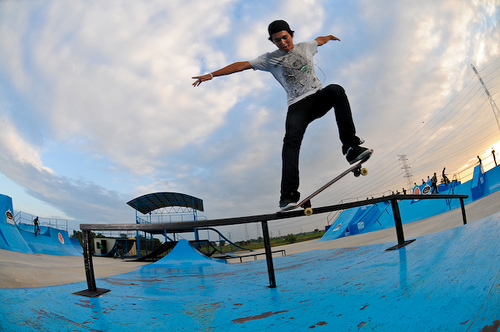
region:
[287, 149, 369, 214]
white skateboard with yellow wheels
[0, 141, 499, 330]
blue and grey skatepark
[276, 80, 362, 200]
black jeans on boy skateboarding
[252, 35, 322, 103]
white tee shirt with black writing on boy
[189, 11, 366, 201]
dark haired boy skateboarding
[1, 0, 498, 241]
blue sky with swirling white clouds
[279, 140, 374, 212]
black and white sneakers on boy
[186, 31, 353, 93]
arms of boy extended over skate park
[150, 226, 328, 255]
green grass and trees in background around skate park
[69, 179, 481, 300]
black metal ramp for skateboard launching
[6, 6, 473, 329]
picture taken outdoors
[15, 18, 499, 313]
picture taken during the day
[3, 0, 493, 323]
the sun is behind the clouds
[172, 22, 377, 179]
a boy on a skateboard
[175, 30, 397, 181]
the boy is doing a trick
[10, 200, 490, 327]
a large skateboard park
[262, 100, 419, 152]
the boys wears black pants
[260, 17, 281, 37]
the boy wears a black hat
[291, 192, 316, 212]
the wheel is white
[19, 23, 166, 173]
the day is partially cloudy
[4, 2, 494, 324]
a boy is on a skateboard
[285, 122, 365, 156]
the boarder wears pants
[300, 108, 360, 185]
the pants are black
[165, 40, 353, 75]
the man's arms are stetched out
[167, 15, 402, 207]
the man is balancing himself on the railing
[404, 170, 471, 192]
people standing at the top of the ramp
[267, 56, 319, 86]
the man wears a white shirt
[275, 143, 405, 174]
the man wears sneakers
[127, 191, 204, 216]
a curved metal canopy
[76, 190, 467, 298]
a black metal bench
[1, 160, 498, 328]
a skateboarding area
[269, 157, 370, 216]
a skateboard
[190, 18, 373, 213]
a man standing on a skateboard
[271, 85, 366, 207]
a man wearing black pants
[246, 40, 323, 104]
a man wearing a white T-shirt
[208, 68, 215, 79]
mn wearing a silver bracelet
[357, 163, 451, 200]
people standing on top of a blue skateboarding ramp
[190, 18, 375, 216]
a man on equilibrium on a skateboard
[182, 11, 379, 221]
a skateboarder in action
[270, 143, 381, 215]
a skateboard the guy is using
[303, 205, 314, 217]
a wheel of a skateboard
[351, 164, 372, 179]
wheels of the skateboard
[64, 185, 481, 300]
a skateboard rails the guy is using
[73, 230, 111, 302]
a leg of a skateboard rail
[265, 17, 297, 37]
a hat the guy is wearing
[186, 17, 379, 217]
a skateboarder on the rails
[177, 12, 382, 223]
a skateboarder with clouds and sky in the background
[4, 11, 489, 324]
a skateboarder in the skateboard park